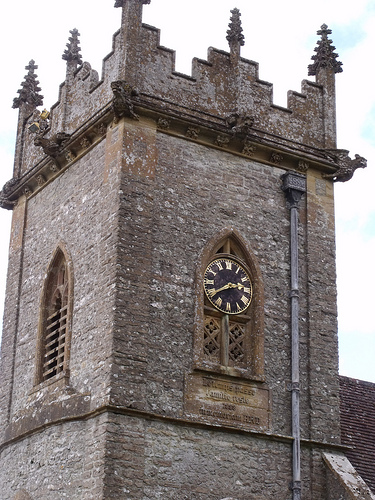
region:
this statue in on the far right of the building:
[311, 133, 370, 187]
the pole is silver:
[286, 331, 305, 437]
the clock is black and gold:
[204, 257, 253, 323]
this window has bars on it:
[20, 231, 91, 397]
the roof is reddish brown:
[347, 392, 367, 425]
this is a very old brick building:
[122, 280, 168, 319]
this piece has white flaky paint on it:
[317, 445, 366, 488]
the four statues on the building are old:
[25, 72, 371, 189]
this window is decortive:
[182, 308, 269, 373]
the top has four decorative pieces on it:
[23, 4, 371, 124]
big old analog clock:
[199, 249, 256, 323]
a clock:
[193, 244, 284, 392]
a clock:
[183, 180, 267, 368]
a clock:
[191, 146, 268, 342]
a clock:
[169, 170, 255, 448]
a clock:
[180, 125, 291, 410]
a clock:
[160, 128, 236, 447]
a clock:
[214, 173, 264, 419]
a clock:
[172, 131, 270, 373]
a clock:
[201, 195, 258, 375]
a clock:
[186, 154, 289, 460]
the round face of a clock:
[201, 255, 257, 317]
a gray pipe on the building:
[273, 169, 309, 498]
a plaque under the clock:
[182, 368, 277, 433]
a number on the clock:
[222, 258, 234, 271]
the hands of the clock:
[206, 278, 248, 297]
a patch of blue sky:
[304, 0, 374, 56]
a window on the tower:
[23, 234, 80, 392]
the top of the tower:
[4, 0, 348, 135]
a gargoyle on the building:
[316, 140, 369, 183]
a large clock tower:
[0, 0, 349, 499]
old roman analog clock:
[202, 252, 251, 318]